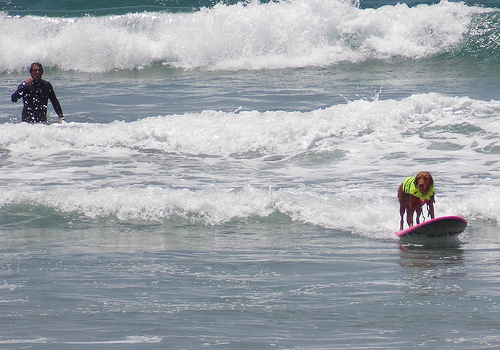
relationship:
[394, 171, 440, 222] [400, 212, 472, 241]
dog on surfboard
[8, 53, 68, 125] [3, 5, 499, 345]
man in water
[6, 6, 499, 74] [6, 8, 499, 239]
wave in ocean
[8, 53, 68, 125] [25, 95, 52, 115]
man wears wetsuit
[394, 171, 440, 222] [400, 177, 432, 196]
dog wears vest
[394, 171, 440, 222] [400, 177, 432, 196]
dog wearing vest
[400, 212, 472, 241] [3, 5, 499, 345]
surfboard in water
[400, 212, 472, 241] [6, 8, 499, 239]
surfboard in ocean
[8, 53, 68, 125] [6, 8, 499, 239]
man in ocean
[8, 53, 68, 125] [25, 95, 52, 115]
man wearing wetsuit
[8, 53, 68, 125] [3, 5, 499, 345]
man standing in water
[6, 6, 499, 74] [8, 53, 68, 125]
wave behind man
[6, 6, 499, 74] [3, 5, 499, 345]
wave in water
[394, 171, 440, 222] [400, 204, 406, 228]
dog has leg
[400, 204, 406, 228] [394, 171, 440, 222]
leg of dog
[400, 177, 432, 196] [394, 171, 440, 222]
vest on dog